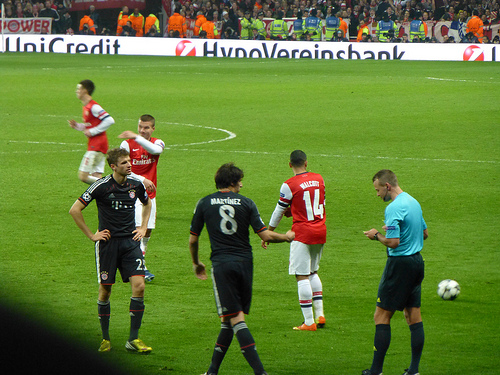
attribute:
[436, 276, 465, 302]
soccerball — white, black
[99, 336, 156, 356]
cleats — yelllow, yellow, white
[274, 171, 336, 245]
shirt — red, white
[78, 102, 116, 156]
shirt — red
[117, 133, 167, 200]
shirt — red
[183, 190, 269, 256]
shirt — blue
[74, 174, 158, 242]
shirt — blue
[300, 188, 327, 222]
number — fourteen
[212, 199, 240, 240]
number — eight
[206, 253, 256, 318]
shorts — black, blue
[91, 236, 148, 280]
shorts — black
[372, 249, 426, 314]
shorts — black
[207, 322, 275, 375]
long socks — blue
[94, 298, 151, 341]
long socks — blue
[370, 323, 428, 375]
long socks — blue